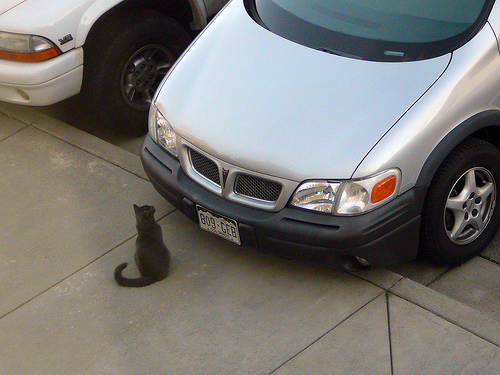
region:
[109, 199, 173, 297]
one black cat sitting on pavement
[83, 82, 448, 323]
black cat sitting in front of silver car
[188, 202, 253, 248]
black and white car license plate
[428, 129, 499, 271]
one round black car wheel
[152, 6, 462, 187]
one shiny gray metal car hood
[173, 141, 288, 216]
one grill of silver sedan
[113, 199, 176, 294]
one cat with tail curved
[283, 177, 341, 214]
one shiny car headlight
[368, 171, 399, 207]
one rectangular shaped car light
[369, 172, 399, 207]
one orange car light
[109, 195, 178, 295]
A cat sitting down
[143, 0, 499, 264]
A silver car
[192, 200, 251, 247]
A license plate on a car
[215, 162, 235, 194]
A logo of a car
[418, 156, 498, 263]
A wheel on a car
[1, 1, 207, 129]
A white car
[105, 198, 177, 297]
A grey cat sitting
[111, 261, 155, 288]
Grey tail of a cat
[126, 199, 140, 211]
An ear of cat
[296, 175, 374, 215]
Headlight of a car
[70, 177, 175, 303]
the cat is black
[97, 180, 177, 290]
the cat is black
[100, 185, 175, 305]
the cat is black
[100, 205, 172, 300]
the cat is black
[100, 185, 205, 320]
the cat is black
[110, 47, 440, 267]
the car is silver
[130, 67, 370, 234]
the car is silver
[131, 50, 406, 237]
the car is silver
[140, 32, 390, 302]
the car is silver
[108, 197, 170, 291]
a grey cat sitting next to a car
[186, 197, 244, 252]
a colorado license plate that says 809 GEB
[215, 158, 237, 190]
a red pontiac logo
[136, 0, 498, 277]
a silver pontiac van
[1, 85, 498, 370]
a concrete side walk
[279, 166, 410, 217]
a silver headlight of a van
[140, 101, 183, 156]
a silver headlight of a van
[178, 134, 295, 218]
a silver grill of a van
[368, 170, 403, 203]
on orange turn signal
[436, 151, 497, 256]
a silver rim on a van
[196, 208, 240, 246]
green and white license plate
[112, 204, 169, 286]
gray cat on sidewalk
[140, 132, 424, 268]
gray plastic car bumper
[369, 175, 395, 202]
automobile left turn signal cover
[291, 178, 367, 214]
automobile left headlights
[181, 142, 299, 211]
automobile grille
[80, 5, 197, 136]
black automobile tire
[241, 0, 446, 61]
automobile wraparound glass windshield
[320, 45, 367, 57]
recessed automobile windshield wiper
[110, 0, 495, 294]
cat sits on sidewalk looking at car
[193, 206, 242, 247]
the license plate is white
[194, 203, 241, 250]
the license plate is green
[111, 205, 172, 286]
the black cat is sitting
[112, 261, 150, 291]
the tail on the cat is black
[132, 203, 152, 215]
the ars on the cat are black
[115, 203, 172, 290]
the cat is looking at the car